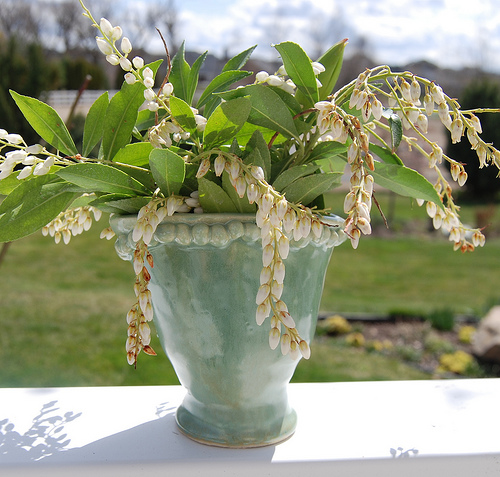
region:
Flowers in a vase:
[35, 122, 250, 432]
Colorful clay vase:
[117, 217, 344, 432]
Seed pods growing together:
[233, 176, 329, 356]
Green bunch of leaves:
[52, 102, 192, 225]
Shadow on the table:
[25, 394, 92, 469]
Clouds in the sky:
[220, 2, 447, 61]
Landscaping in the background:
[329, 273, 494, 353]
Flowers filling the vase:
[87, 37, 432, 246]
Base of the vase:
[173, 378, 324, 465]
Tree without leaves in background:
[3, 1, 170, 73]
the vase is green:
[228, 374, 243, 402]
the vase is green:
[234, 377, 249, 419]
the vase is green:
[224, 363, 237, 393]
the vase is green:
[246, 390, 256, 415]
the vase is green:
[237, 398, 257, 438]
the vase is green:
[210, 403, 232, 438]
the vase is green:
[235, 390, 254, 411]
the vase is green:
[241, 403, 258, 426]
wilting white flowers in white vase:
[124, 215, 166, 362]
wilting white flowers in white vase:
[254, 221, 315, 363]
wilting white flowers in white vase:
[51, 188, 96, 250]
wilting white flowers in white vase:
[314, 110, 381, 240]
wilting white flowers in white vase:
[384, 165, 480, 255]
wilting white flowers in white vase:
[341, 59, 465, 154]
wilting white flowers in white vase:
[90, 22, 179, 126]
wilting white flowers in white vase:
[221, 48, 312, 138]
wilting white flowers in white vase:
[172, 277, 237, 372]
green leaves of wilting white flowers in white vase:
[78, 92, 162, 166]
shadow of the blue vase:
[91, 430, 173, 473]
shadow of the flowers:
[6, 398, 75, 454]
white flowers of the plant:
[252, 223, 322, 365]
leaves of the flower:
[15, 86, 138, 193]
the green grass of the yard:
[17, 239, 106, 364]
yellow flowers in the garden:
[436, 343, 480, 374]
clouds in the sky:
[361, 10, 498, 61]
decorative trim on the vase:
[179, 221, 260, 248]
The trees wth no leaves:
[6, 6, 86, 94]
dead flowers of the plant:
[357, 133, 383, 174]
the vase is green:
[224, 398, 238, 434]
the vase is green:
[228, 408, 244, 423]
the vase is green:
[204, 386, 224, 428]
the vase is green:
[228, 398, 245, 435]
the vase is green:
[232, 425, 252, 445]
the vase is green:
[214, 412, 241, 450]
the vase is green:
[224, 425, 245, 446]